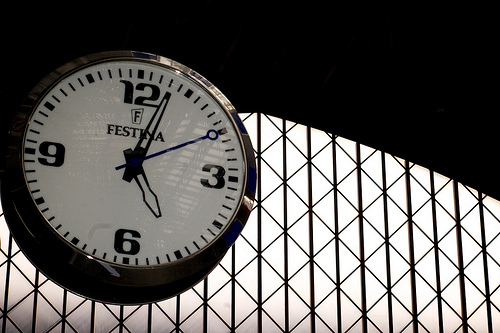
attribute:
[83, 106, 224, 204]
hands — minute, hour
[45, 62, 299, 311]
clock — white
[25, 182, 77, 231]
lines — small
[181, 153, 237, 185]
numbers — black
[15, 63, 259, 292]
clock — white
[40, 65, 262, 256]
clock — round, white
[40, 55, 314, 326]
clock — silver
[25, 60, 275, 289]
clock — white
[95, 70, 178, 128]
numbers — black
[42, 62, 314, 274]
clock — reading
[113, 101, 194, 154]
letters — black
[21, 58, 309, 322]
clock — hanging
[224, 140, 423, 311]
grate — metal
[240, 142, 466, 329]
grate — metal, behind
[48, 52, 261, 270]
clock — silver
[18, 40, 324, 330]
clock — silver, white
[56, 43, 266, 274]
clock — round, white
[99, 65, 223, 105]
numbers — black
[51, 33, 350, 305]
clock — 12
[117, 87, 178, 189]
hand — black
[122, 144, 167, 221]
hand — black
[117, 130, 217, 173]
hand — black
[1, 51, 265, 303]
frame — black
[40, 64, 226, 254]
numbers — black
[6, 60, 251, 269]
clock face — white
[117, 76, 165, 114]
number — black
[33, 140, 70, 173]
number — black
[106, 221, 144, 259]
number — black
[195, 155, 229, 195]
number — black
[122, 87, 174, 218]
hands — black, white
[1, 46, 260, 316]
clock — large